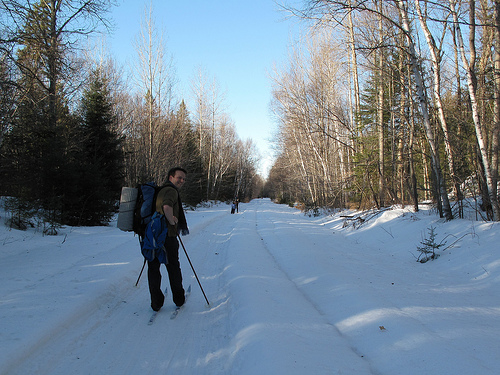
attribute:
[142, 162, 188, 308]
person — skiing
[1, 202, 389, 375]
road — snowy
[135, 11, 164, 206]
tree — winter, brown, leafless, little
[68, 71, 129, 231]
evergreen — bronw, brown, pine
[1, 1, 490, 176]
sky — light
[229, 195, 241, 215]
man — skiing, distant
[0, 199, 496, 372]
ground — snowy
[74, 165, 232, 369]
trail — snowy